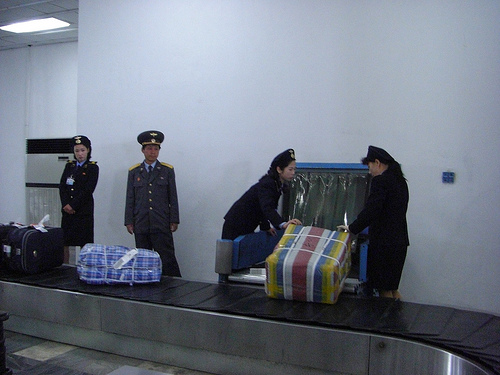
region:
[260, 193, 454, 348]
The ladies are pushing luggage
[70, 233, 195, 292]
The bag is blue on the coveyor belt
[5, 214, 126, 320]
The black bag is on the conveyor belt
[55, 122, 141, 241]
The woman is in a uniform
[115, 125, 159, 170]
The man is wearing a hat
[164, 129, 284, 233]
The woman is wearing a uniform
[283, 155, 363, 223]
There is a plastic door for the luggage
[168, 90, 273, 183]
The wall is behind the employees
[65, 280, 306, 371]
The conveyor belt is black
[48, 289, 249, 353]
The side of the belt is silver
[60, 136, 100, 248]
woman standing in black uniform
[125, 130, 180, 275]
man standing with black uniform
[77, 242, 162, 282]
blue bag in conveyor belt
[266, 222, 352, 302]
multicolored bag in conveyor belt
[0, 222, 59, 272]
black bag in conveyor belt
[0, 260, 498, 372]
black conveyor belt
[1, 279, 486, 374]
metal part in conveyor belt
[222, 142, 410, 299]
two women holding bag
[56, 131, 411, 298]
four people standing in airport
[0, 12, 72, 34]
ceiling lights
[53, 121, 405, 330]
They are checking bags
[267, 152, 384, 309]
Bags come from the wall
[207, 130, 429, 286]
Both are holding a bag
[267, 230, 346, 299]
The bag has many colors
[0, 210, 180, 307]
Two bags were checked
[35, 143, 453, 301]
They all have uniforms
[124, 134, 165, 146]
His hat is grey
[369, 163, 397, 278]
her outfit is black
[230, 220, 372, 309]
the bag is blue red white and yellow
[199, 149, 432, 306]
their outfits are black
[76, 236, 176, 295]
luggage on a carrier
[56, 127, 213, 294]
workers at an airport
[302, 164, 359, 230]
door to the luggage transporter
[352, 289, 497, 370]
luggage transporter in an airline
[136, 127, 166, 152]
hat on a man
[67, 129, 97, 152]
hat on a woman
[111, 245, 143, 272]
tag on a piece of luggage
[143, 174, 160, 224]
buttons on a jacket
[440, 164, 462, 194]
sign on a wall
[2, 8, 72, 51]
light on the ceiling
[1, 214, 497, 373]
Bags on a carousel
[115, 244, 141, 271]
White tag on a bag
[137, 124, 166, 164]
Hat on man's head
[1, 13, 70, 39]
A light on the ceiling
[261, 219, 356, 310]
The box is striped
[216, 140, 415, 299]
Two women wearing black uniforms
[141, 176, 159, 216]
Buttons on a jacket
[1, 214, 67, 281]
Black bag on a carousel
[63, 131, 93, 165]
Woman has black hair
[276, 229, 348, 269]
Two white ropes around a box